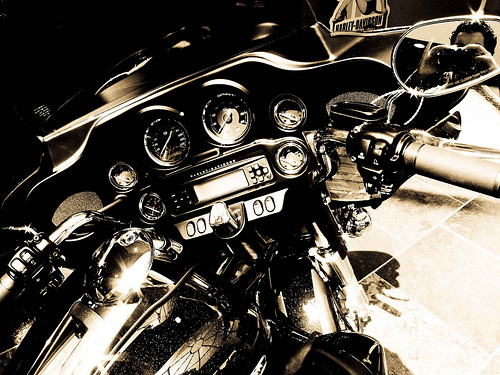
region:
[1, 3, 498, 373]
the photograph is black and white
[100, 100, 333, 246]
many motorcycle dials are seen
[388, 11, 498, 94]
a rear view mirror is on the right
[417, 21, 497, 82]
man taking picture can be seen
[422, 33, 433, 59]
the man has his finger extended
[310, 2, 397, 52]
a company logo is seen on background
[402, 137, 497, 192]
handle from handlebars can be seen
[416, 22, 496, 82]
the man is holding camera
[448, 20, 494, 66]
the man has very dark hair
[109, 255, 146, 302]
a sparkle of light is being reflected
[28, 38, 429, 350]
control panel on front of motorcycle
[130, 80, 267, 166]
circles with hands showing measurements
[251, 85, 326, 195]
one circle on top of the other circle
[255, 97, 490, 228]
handlebar sticking out from the control panel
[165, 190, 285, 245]
metal knob in the middle of four buttons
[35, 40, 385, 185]
curved outer edge of control panel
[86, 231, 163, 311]
round attachment reflecting light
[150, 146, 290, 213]
rectangular panel with screen in middle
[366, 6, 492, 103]
mirror showing person holding binoculars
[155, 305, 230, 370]
circle with spokes around it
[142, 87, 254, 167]
silver round speed dials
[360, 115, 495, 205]
motorcycle braking gear visible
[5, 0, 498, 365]
black and white picture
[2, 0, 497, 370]
silver Harley Davidson bike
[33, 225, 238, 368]
silver motorcycle gas cap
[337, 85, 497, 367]
white tiled ceramic floor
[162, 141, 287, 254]
sound system below speedometer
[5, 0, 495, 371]
black background behind bike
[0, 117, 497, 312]
bike handles with brakes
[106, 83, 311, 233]
round electronic bike dials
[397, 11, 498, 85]
Side view mirror on the motorcycle.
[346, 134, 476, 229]
Right handle on the bike.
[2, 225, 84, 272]
Left handle on the bike.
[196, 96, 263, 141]
Odometer on the bike.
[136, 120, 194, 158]
Other gauge on the bike.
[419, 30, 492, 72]
Person in the side view mirror of the bike.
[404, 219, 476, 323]
Flooring where the bike is parked.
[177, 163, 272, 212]
Radio on the bike.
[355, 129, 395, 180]
Buttons on the bike handle.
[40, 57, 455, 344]
Motorcycle that is parked on the street.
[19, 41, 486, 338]
front of a motorcycle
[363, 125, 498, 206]
motorcycle handlebar on the right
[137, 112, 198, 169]
black speedometer of the motorcycle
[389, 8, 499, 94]
shiny mirror of the motorcycle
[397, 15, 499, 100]
reflection of photographer in mirror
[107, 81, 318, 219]
chrome and black gauges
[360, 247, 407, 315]
shadows cast on the ground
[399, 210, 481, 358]
overexposed concrete on the ground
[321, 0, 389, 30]
motorcycle logo at the top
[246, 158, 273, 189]
chrome buttons on motorcycle